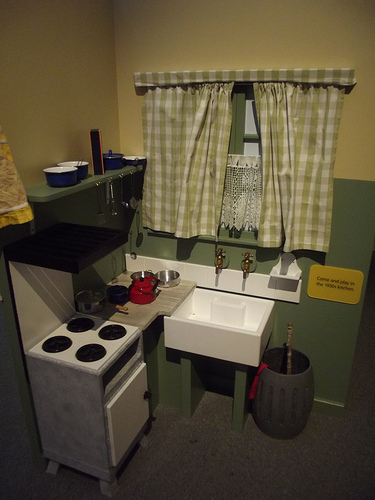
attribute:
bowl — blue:
[44, 166, 78, 186]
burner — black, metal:
[40, 335, 72, 352]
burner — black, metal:
[63, 317, 94, 332]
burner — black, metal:
[95, 324, 126, 339]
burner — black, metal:
[76, 342, 106, 363]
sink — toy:
[181, 292, 268, 354]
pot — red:
[125, 269, 159, 311]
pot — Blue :
[103, 146, 128, 170]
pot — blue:
[40, 163, 79, 189]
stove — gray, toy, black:
[23, 313, 154, 493]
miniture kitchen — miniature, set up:
[1, 67, 350, 499]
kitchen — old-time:
[16, 44, 373, 410]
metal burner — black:
[51, 312, 118, 357]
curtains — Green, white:
[124, 60, 358, 264]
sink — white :
[160, 285, 277, 369]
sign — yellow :
[307, 264, 363, 303]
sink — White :
[165, 281, 279, 371]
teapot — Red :
[125, 270, 161, 308]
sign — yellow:
[304, 261, 368, 308]